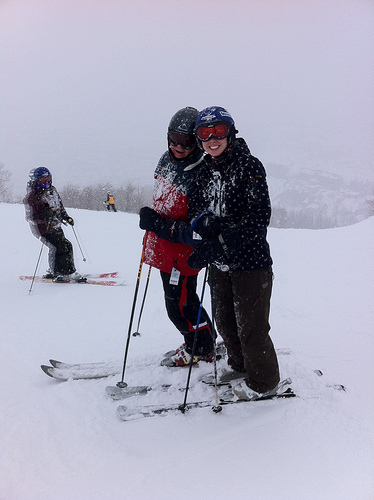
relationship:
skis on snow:
[34, 358, 307, 431] [71, 409, 372, 488]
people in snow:
[12, 108, 288, 394] [71, 409, 372, 488]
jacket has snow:
[180, 145, 260, 278] [71, 409, 372, 488]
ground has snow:
[267, 239, 365, 496] [71, 409, 372, 488]